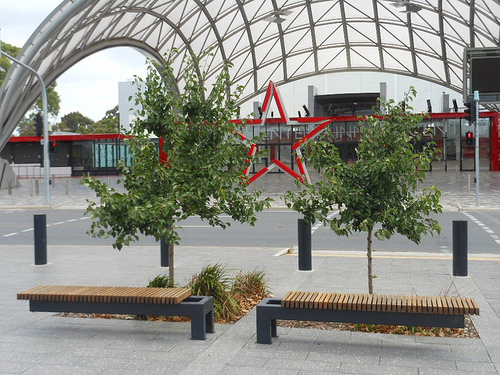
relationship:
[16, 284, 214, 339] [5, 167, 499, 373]
bed on ground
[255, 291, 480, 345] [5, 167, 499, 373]
bed on ground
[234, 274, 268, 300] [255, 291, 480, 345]
grass on bed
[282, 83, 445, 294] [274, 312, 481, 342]
tree on bed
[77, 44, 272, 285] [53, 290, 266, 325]
tree on bed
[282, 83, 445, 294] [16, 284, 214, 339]
tree on bed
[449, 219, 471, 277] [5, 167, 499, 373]
pole in ground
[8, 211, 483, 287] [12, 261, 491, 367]
black poles are in sidewalk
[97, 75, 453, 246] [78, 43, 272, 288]
leaves on tree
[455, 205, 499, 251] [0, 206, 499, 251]
white lines on pavement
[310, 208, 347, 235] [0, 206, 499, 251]
white lines on pavement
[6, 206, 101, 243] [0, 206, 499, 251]
white lines on pavement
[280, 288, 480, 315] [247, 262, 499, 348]
slats on bench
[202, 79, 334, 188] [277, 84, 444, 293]
star behind tree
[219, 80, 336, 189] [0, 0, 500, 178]
star in front of building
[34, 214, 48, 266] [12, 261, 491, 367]
black poles on sidewalk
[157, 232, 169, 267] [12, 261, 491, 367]
pole on sidewalk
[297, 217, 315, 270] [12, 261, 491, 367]
pole on sidewalk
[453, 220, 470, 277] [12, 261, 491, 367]
pole on sidewalk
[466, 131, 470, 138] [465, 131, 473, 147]
light on traffic light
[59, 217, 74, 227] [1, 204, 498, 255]
lines drawn on street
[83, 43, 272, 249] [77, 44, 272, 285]
leaves on tree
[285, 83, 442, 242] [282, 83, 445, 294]
leaves on tree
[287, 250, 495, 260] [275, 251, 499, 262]
line near curb